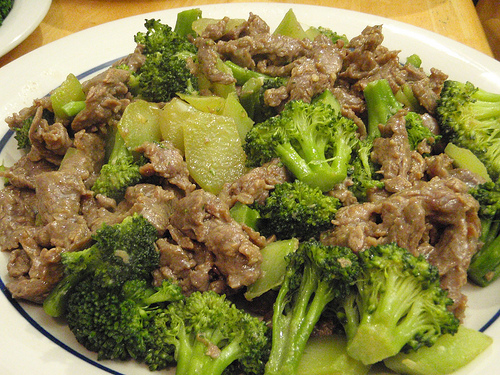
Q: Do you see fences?
A: No, there are no fences.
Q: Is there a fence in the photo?
A: No, there are no fences.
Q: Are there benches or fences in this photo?
A: No, there are no fences or benches.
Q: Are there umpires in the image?
A: No, there are no umpires.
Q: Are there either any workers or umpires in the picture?
A: No, there are no umpires or workers.